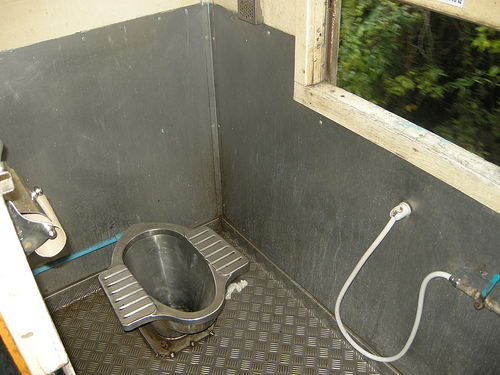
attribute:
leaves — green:
[394, 73, 419, 93]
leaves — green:
[342, 1, 499, 164]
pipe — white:
[22, 187, 77, 264]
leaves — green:
[349, 28, 454, 108]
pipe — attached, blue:
[33, 227, 125, 280]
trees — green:
[341, 12, 486, 130]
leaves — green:
[417, 68, 447, 99]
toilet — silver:
[104, 222, 249, 352]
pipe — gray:
[447, 267, 498, 324]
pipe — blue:
[474, 273, 499, 310]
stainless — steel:
[225, 322, 307, 367]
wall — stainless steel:
[4, 4, 264, 311]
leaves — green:
[333, 0, 499, 173]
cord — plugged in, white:
[331, 198, 457, 363]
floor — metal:
[42, 193, 415, 373]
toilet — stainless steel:
[97, 208, 245, 338]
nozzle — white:
[383, 201, 417, 222]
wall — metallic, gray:
[11, 53, 426, 283]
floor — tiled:
[148, 103, 185, 125]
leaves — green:
[417, 73, 440, 96]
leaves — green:
[386, 74, 409, 94]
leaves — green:
[470, 32, 490, 50]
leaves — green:
[351, 30, 379, 53]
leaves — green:
[398, 5, 424, 27]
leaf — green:
[351, 25, 365, 37]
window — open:
[324, 2, 451, 125]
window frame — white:
[294, 0, 498, 219]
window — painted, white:
[294, 0, 498, 211]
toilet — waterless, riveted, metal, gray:
[94, 214, 259, 356]